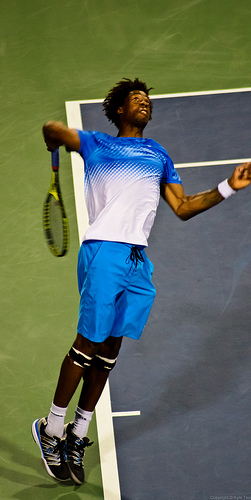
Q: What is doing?
A: Jumping.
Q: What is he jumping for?
A: Tennis ball.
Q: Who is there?
A: Tennis player.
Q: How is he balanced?
A: Tip-toe.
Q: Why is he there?
A: Playing tennis.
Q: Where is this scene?
A: Tennis court.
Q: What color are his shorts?
A: Blue.